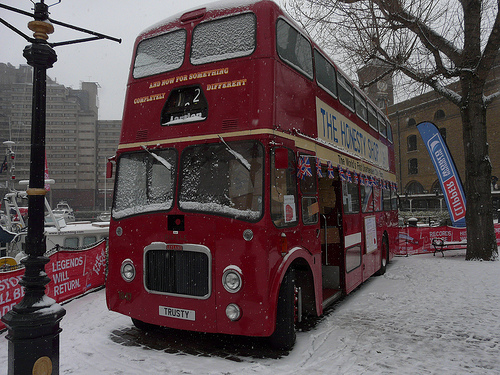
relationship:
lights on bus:
[115, 226, 253, 320] [107, 1, 401, 351]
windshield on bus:
[113, 143, 264, 223] [107, 1, 401, 351]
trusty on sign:
[163, 306, 190, 320] [157, 306, 196, 320]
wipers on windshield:
[142, 135, 252, 171] [113, 143, 264, 223]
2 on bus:
[193, 88, 202, 103] [107, 1, 401, 351]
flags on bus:
[298, 156, 399, 194] [107, 1, 401, 351]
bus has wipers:
[107, 1, 401, 351] [142, 135, 252, 171]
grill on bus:
[146, 250, 210, 296] [107, 1, 401, 351]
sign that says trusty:
[157, 306, 196, 320] [163, 306, 190, 320]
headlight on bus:
[223, 269, 242, 293] [107, 1, 401, 351]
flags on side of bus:
[298, 156, 399, 194] [107, 1, 401, 351]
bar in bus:
[320, 212, 329, 266] [107, 1, 401, 351]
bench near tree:
[431, 239, 468, 258] [281, 1, 499, 260]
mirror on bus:
[270, 140, 290, 171] [107, 1, 401, 351]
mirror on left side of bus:
[106, 156, 116, 178] [107, 1, 401, 351]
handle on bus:
[316, 230, 321, 240] [107, 1, 401, 351]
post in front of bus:
[2, 3, 122, 373] [107, 1, 401, 351]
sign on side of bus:
[315, 97, 391, 171] [107, 1, 401, 351]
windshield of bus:
[113, 143, 264, 223] [107, 1, 401, 351]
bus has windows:
[107, 1, 401, 351] [113, 10, 398, 273]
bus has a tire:
[107, 1, 401, 351] [271, 265, 298, 349]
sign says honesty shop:
[315, 97, 391, 171] [319, 108, 380, 162]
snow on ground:
[0, 246, 499, 374] [1, 248, 499, 373]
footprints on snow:
[0, 247, 499, 374] [0, 246, 499, 374]